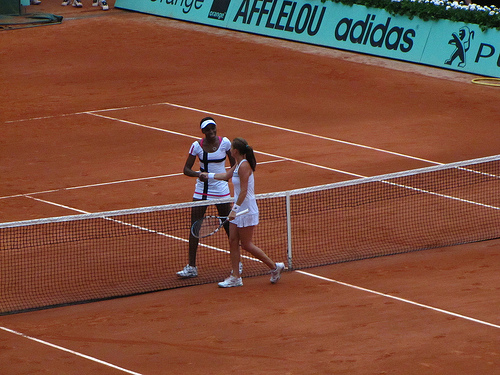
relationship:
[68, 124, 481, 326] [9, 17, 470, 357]
long net on court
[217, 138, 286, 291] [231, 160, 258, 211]
lady in shirt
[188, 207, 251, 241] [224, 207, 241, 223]
racket in left hand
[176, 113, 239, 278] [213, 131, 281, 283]
lady shaking hands with opponent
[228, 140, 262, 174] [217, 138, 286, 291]
hair of lady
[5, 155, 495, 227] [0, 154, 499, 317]
top of long net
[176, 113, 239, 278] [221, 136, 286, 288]
lady shaking hands with player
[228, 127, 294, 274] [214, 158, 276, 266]
lady wearing dress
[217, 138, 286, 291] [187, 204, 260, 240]
lady holding tennis racket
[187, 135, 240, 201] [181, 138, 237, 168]
dress has short sleeves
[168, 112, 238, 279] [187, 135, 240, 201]
lady wearing dress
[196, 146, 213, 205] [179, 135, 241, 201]
stripe on dress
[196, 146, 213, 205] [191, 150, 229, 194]
stripe on dress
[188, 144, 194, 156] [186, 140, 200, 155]
stripe on sleeve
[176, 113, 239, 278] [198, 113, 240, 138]
lady wearing visor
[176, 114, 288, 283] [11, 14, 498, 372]
athletes on court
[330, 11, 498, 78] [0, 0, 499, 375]
ads on court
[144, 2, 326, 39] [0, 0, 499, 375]
ads on court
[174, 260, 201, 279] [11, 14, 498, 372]
tennis sneaker on court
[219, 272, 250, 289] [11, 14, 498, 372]
shoe on court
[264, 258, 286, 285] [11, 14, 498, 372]
sneaker on court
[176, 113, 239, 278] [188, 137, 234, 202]
lady wearing tennis dress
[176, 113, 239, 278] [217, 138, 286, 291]
lady shakes with lady